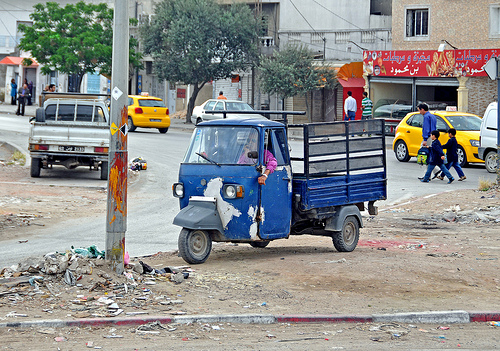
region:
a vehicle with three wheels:
[160, 102, 411, 276]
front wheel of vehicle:
[170, 225, 220, 270]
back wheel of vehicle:
[328, 211, 368, 258]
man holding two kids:
[400, 89, 468, 193]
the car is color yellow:
[125, 91, 176, 143]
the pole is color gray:
[100, 0, 140, 268]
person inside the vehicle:
[160, 103, 404, 270]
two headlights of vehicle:
[168, 182, 242, 207]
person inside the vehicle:
[180, 112, 290, 199]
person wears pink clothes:
[221, 121, 282, 191]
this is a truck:
[158, 65, 414, 293]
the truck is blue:
[158, 87, 368, 287]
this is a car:
[385, 90, 475, 187]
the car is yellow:
[383, 105, 488, 182]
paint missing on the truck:
[185, 155, 285, 275]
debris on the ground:
[3, 227, 211, 347]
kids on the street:
[423, 110, 473, 189]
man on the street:
[402, 90, 437, 157]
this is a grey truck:
[22, 79, 126, 176]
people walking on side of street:
[335, 80, 376, 140]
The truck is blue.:
[176, 117, 396, 257]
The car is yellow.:
[393, 103, 488, 166]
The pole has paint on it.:
[108, 86, 133, 278]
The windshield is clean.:
[185, 128, 267, 166]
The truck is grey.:
[21, 87, 118, 176]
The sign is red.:
[360, 44, 497, 72]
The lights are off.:
[173, 179, 243, 204]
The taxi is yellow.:
[118, 89, 172, 129]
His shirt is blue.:
[340, 98, 358, 115]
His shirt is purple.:
[230, 146, 280, 181]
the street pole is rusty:
[108, 2, 138, 269]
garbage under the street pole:
[40, 242, 126, 306]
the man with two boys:
[404, 104, 470, 184]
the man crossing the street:
[409, 100, 472, 187]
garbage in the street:
[124, 151, 149, 174]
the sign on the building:
[359, 47, 498, 79]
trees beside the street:
[147, 6, 314, 104]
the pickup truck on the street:
[19, 88, 124, 175]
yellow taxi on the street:
[124, 91, 172, 137]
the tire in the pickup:
[31, 106, 48, 126]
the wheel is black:
[308, 204, 372, 275]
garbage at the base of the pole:
[3, 211, 224, 343]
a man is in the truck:
[202, 110, 301, 255]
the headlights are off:
[156, 163, 249, 215]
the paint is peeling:
[195, 165, 267, 250]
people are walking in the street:
[397, 80, 480, 198]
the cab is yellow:
[95, 76, 173, 135]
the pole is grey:
[84, 0, 153, 275]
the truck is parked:
[140, 71, 445, 310]